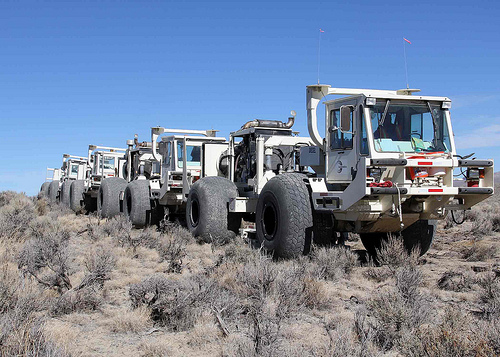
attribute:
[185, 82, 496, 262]
machine — heavy duty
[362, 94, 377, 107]
headlight — top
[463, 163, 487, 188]
fire extinguisher — small, red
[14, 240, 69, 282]
scrub brush — dry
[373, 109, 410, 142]
man — inside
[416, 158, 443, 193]
reflectors — red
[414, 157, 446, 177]
reflector — red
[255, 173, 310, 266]
tire — black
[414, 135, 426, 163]
paper — small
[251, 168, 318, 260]
tire — black, big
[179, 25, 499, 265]
industrial vehicle — large, white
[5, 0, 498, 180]
sky — bright, clear, blue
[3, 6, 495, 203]
sky — bright, sunny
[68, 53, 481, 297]
convoy — large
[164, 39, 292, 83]
sky — cloudless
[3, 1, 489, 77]
skies — calm, blue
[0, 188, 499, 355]
desert — dry, arid, large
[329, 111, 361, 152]
mirror — side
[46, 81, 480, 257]
vehicles — heavy duty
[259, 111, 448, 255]
truck — first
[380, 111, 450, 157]
vest — orange